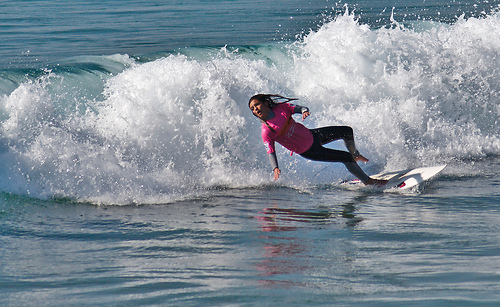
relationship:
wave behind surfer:
[8, 4, 498, 188] [228, 75, 449, 206]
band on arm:
[267, 158, 283, 166] [249, 140, 314, 210]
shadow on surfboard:
[279, 176, 381, 233] [326, 131, 441, 209]